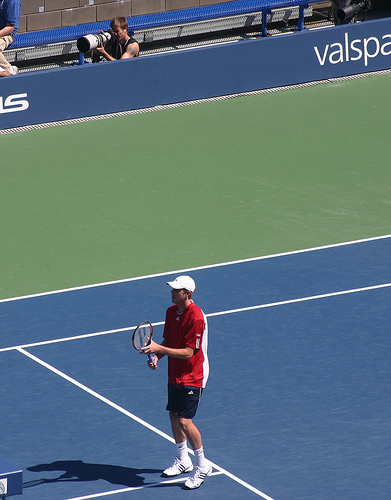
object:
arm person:
[123, 310, 215, 383]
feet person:
[147, 422, 260, 500]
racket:
[130, 318, 157, 368]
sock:
[192, 446, 205, 465]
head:
[169, 275, 198, 303]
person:
[135, 274, 210, 487]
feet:
[165, 453, 214, 492]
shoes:
[160, 449, 216, 491]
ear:
[186, 292, 195, 298]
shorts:
[140, 385, 196, 412]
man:
[132, 273, 212, 490]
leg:
[180, 418, 208, 468]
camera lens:
[77, 30, 114, 54]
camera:
[72, 29, 115, 54]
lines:
[112, 234, 336, 286]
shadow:
[10, 456, 168, 490]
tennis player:
[134, 245, 226, 499]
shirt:
[156, 297, 214, 389]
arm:
[151, 341, 203, 360]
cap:
[164, 275, 195, 291]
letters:
[315, 31, 357, 75]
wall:
[85, 33, 236, 115]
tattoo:
[164, 346, 190, 362]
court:
[4, 108, 375, 495]